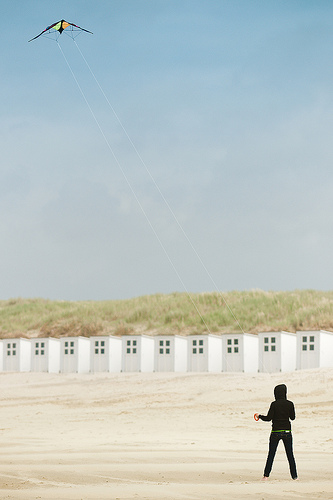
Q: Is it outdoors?
A: Yes, it is outdoors.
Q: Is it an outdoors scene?
A: Yes, it is outdoors.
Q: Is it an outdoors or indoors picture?
A: It is outdoors.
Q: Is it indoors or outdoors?
A: It is outdoors.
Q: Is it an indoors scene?
A: No, it is outdoors.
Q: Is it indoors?
A: No, it is outdoors.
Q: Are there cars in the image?
A: No, there are no cars.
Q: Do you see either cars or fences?
A: No, there are no cars or fences.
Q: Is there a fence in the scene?
A: No, there are no fences.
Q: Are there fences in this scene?
A: No, there are no fences.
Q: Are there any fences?
A: No, there are no fences.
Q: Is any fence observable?
A: No, there are no fences.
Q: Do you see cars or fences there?
A: No, there are no fences or cars.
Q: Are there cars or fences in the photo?
A: No, there are no fences or cars.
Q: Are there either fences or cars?
A: No, there are no fences or cars.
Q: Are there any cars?
A: No, there are no cars.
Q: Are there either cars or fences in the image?
A: No, there are no cars or fences.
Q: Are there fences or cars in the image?
A: No, there are no cars or fences.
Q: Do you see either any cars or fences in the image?
A: No, there are no cars or fences.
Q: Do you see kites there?
A: Yes, there is a kite.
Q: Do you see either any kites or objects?
A: Yes, there is a kite.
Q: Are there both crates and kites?
A: No, there is a kite but no crates.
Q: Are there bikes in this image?
A: No, there are no bikes.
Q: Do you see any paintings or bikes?
A: No, there are no bikes or paintings.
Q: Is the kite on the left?
A: Yes, the kite is on the left of the image.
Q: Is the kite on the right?
A: No, the kite is on the left of the image.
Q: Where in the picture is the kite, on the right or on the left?
A: The kite is on the left of the image.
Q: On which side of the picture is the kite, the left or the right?
A: The kite is on the left of the image.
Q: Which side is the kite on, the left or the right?
A: The kite is on the left of the image.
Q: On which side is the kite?
A: The kite is on the left of the image.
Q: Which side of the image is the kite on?
A: The kite is on the left of the image.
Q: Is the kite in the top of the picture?
A: Yes, the kite is in the top of the image.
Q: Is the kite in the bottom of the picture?
A: No, the kite is in the top of the image.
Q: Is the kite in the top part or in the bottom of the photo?
A: The kite is in the top of the image.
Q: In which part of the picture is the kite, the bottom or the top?
A: The kite is in the top of the image.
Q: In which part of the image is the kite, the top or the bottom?
A: The kite is in the top of the image.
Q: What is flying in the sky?
A: The kite is flying in the sky.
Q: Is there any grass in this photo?
A: Yes, there is grass.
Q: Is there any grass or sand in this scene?
A: Yes, there is grass.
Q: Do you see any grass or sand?
A: Yes, there is grass.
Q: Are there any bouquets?
A: No, there are no bouquets.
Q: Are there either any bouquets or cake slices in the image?
A: No, there are no bouquets or cake slices.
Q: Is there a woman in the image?
A: Yes, there is a woman.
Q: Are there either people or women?
A: Yes, there is a woman.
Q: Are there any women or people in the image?
A: Yes, there is a woman.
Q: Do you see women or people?
A: Yes, there is a woman.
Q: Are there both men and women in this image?
A: No, there is a woman but no men.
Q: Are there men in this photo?
A: No, there are no men.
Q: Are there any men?
A: No, there are no men.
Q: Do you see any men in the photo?
A: No, there are no men.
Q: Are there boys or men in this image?
A: No, there are no men or boys.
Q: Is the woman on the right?
A: Yes, the woman is on the right of the image.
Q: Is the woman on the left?
A: No, the woman is on the right of the image.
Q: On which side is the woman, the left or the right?
A: The woman is on the right of the image.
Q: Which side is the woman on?
A: The woman is on the right of the image.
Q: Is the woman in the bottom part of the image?
A: Yes, the woman is in the bottom of the image.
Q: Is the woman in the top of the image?
A: No, the woman is in the bottom of the image.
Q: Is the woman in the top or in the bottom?
A: The woman is in the bottom of the image.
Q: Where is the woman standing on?
A: The woman is standing on the beach.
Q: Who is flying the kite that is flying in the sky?
A: The woman is flying the kite.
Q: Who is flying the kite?
A: The woman is flying the kite.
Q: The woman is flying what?
A: The woman is flying the kite.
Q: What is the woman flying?
A: The woman is flying the kite.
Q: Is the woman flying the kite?
A: Yes, the woman is flying the kite.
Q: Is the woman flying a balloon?
A: No, the woman is flying the kite.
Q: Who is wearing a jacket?
A: The woman is wearing a jacket.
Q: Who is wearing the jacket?
A: The woman is wearing a jacket.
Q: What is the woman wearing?
A: The woman is wearing a jacket.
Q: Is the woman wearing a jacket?
A: Yes, the woman is wearing a jacket.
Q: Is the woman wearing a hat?
A: No, the woman is wearing a jacket.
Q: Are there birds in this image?
A: No, there are no birds.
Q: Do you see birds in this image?
A: No, there are no birds.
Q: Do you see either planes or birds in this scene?
A: No, there are no birds or planes.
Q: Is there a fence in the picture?
A: No, there are no fences.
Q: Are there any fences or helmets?
A: No, there are no fences or helmets.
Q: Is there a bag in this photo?
A: No, there are no bags.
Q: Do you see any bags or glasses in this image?
A: No, there are no bags or glasses.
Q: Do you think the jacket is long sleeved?
A: Yes, the jacket is long sleeved.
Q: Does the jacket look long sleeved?
A: Yes, the jacket is long sleeved.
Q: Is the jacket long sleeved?
A: Yes, the jacket is long sleeved.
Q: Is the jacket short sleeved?
A: No, the jacket is long sleeved.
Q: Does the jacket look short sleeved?
A: No, the jacket is long sleeved.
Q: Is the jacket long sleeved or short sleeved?
A: The jacket is long sleeved.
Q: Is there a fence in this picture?
A: No, there are no fences.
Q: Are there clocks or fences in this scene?
A: No, there are no fences or clocks.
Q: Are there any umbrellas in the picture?
A: No, there are no umbrellas.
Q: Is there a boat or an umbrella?
A: No, there are no umbrellas or boats.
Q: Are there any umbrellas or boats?
A: No, there are no umbrellas or boats.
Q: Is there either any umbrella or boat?
A: No, there are no umbrellas or boats.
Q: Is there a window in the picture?
A: Yes, there is a window.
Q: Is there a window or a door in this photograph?
A: Yes, there is a window.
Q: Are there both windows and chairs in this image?
A: No, there is a window but no chairs.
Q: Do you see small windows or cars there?
A: Yes, there is a small window.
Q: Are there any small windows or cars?
A: Yes, there is a small window.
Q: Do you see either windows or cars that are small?
A: Yes, the window is small.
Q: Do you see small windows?
A: Yes, there is a small window.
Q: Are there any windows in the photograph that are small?
A: Yes, there is a window that is small.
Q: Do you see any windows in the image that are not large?
A: Yes, there is a small window.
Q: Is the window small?
A: Yes, the window is small.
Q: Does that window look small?
A: Yes, the window is small.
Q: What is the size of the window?
A: The window is small.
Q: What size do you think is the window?
A: The window is small.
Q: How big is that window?
A: The window is small.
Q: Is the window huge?
A: No, the window is small.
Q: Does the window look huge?
A: No, the window is small.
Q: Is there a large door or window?
A: No, there is a window but it is small.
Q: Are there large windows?
A: No, there is a window but it is small.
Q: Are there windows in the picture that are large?
A: No, there is a window but it is small.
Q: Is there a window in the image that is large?
A: No, there is a window but it is small.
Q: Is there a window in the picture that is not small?
A: No, there is a window but it is small.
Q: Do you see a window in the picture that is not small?
A: No, there is a window but it is small.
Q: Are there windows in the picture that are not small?
A: No, there is a window but it is small.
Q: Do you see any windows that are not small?
A: No, there is a window but it is small.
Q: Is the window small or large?
A: The window is small.